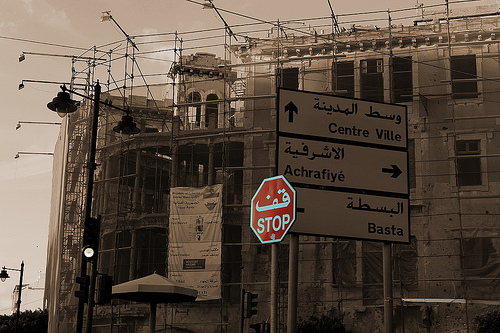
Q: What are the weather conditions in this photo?
A: It is cloudy.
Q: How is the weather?
A: It is cloudy.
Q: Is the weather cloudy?
A: Yes, it is cloudy.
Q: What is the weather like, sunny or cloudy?
A: It is cloudy.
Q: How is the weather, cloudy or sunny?
A: It is cloudy.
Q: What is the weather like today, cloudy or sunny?
A: It is cloudy.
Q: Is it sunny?
A: No, it is cloudy.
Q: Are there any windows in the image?
A: Yes, there are windows.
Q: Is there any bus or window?
A: Yes, there are windows.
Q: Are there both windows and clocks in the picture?
A: No, there are windows but no clocks.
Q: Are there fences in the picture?
A: No, there are no fences.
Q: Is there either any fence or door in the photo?
A: No, there are no fences or doors.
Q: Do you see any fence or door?
A: No, there are no fences or doors.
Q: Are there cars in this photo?
A: No, there are no cars.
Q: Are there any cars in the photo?
A: No, there are no cars.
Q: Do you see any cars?
A: No, there are no cars.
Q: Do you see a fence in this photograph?
A: No, there are no fences.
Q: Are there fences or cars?
A: No, there are no fences or cars.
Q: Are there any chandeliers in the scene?
A: No, there are no chandeliers.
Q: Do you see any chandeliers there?
A: No, there are no chandeliers.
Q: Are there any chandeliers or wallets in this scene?
A: No, there are no chandeliers or wallets.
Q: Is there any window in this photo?
A: Yes, there is a window.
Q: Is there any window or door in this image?
A: Yes, there is a window.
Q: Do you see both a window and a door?
A: No, there is a window but no doors.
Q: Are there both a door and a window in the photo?
A: No, there is a window but no doors.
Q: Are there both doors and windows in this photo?
A: No, there is a window but no doors.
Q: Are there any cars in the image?
A: No, there are no cars.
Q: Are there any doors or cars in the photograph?
A: No, there are no cars or doors.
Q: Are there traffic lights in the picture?
A: Yes, there is a traffic light.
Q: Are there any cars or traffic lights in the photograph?
A: Yes, there is a traffic light.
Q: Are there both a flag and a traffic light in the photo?
A: No, there is a traffic light but no flags.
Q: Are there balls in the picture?
A: No, there are no balls.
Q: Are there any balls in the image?
A: No, there are no balls.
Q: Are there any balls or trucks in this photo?
A: No, there are no balls or trucks.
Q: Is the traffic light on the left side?
A: Yes, the traffic light is on the left of the image.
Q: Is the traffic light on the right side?
A: No, the traffic light is on the left of the image.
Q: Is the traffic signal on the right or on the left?
A: The traffic signal is on the left of the image.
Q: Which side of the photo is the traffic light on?
A: The traffic light is on the left of the image.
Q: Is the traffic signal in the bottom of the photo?
A: Yes, the traffic signal is in the bottom of the image.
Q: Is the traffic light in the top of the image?
A: No, the traffic light is in the bottom of the image.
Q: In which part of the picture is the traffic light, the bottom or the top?
A: The traffic light is in the bottom of the image.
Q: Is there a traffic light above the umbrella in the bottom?
A: Yes, there is a traffic light above the umbrella.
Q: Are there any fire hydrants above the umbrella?
A: No, there is a traffic light above the umbrella.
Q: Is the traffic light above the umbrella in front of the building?
A: Yes, the traffic light is above the umbrella.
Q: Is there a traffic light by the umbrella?
A: Yes, there is a traffic light by the umbrella.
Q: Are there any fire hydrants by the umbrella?
A: No, there is a traffic light by the umbrella.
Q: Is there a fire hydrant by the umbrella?
A: No, there is a traffic light by the umbrella.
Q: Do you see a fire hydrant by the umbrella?
A: No, there is a traffic light by the umbrella.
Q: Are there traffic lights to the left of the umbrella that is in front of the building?
A: Yes, there is a traffic light to the left of the umbrella.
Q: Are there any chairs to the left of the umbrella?
A: No, there is a traffic light to the left of the umbrella.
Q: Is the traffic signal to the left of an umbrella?
A: Yes, the traffic signal is to the left of an umbrella.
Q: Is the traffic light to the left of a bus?
A: No, the traffic light is to the left of an umbrella.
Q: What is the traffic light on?
A: The traffic light is on the pole.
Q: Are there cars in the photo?
A: No, there are no cars.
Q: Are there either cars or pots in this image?
A: No, there are no cars or pots.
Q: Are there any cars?
A: No, there are no cars.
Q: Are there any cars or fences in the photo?
A: No, there are no cars or fences.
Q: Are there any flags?
A: No, there are no flags.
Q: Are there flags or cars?
A: No, there are no flags or cars.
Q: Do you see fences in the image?
A: No, there are no fences.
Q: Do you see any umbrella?
A: Yes, there is an umbrella.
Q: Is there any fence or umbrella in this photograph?
A: Yes, there is an umbrella.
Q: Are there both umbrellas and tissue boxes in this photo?
A: No, there is an umbrella but no tissue boxes.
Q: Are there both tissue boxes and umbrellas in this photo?
A: No, there is an umbrella but no tissue boxes.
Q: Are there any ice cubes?
A: No, there are no ice cubes.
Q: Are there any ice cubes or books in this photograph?
A: No, there are no ice cubes or books.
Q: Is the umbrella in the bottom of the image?
A: Yes, the umbrella is in the bottom of the image.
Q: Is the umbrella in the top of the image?
A: No, the umbrella is in the bottom of the image.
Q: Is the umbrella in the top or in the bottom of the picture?
A: The umbrella is in the bottom of the image.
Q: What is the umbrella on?
A: The umbrella is on the pole.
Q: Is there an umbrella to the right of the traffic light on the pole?
A: Yes, there is an umbrella to the right of the traffic light.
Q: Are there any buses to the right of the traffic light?
A: No, there is an umbrella to the right of the traffic light.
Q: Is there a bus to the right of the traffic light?
A: No, there is an umbrella to the right of the traffic light.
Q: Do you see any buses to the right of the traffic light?
A: No, there is an umbrella to the right of the traffic light.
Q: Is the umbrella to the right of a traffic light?
A: Yes, the umbrella is to the right of a traffic light.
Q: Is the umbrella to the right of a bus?
A: No, the umbrella is to the right of a traffic light.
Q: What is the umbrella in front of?
A: The umbrella is in front of the building.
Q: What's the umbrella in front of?
A: The umbrella is in front of the building.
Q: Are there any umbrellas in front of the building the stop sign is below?
A: Yes, there is an umbrella in front of the building.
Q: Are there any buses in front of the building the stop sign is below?
A: No, there is an umbrella in front of the building.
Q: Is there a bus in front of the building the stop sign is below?
A: No, there is an umbrella in front of the building.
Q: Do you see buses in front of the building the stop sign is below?
A: No, there is an umbrella in front of the building.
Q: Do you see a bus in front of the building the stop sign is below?
A: No, there is an umbrella in front of the building.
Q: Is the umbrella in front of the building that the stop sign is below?
A: Yes, the umbrella is in front of the building.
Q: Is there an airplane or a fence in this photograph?
A: No, there are no fences or airplanes.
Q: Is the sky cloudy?
A: Yes, the sky is cloudy.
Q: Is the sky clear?
A: No, the sky is cloudy.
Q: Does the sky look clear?
A: No, the sky is cloudy.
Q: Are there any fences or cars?
A: No, there are no cars or fences.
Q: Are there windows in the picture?
A: Yes, there is a window.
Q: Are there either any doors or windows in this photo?
A: Yes, there is a window.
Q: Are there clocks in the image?
A: No, there are no clocks.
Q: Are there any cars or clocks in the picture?
A: No, there are no clocks or cars.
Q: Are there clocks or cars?
A: No, there are no clocks or cars.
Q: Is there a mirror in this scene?
A: No, there are no mirrors.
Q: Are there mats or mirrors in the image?
A: No, there are no mirrors or mats.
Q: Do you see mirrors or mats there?
A: No, there are no mirrors or mats.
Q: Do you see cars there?
A: No, there are no cars.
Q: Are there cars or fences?
A: No, there are no cars or fences.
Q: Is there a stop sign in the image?
A: Yes, there is a stop sign.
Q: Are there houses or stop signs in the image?
A: Yes, there is a stop sign.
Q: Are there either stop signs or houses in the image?
A: Yes, there is a stop sign.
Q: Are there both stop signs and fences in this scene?
A: No, there is a stop sign but no fences.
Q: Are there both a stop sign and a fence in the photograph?
A: No, there is a stop sign but no fences.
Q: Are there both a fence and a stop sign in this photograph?
A: No, there is a stop sign but no fences.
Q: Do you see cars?
A: No, there are no cars.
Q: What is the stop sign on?
A: The stop sign is on the pole.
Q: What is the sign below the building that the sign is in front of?
A: The sign is a stop sign.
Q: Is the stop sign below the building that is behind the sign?
A: Yes, the stop sign is below the building.